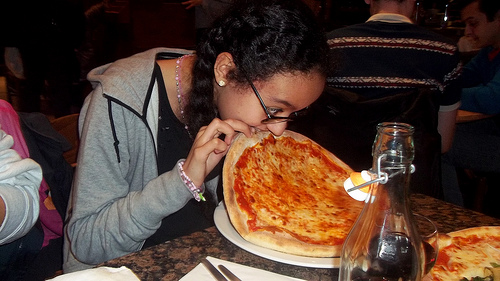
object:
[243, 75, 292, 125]
glasses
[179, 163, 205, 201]
bracelet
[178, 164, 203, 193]
wrist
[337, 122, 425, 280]
bottle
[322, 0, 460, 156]
man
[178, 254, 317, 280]
napkin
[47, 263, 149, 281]
napkin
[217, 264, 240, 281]
silverware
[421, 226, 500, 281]
pizza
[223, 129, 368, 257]
pizza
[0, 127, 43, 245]
sweater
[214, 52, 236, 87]
ear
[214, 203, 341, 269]
plate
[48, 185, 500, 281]
table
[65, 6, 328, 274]
girl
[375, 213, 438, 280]
glass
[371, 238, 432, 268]
wine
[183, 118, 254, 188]
hand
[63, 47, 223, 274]
sweater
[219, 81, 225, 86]
earring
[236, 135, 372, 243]
cheese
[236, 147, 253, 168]
tomato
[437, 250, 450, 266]
tomato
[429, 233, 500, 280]
cheese